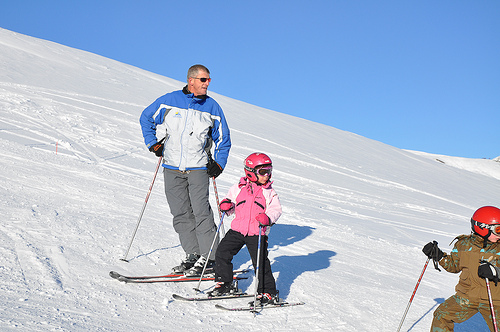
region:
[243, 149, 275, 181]
the helmet is red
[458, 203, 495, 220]
thehelmet is red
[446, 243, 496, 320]
the jacket is brown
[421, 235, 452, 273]
the gloves are black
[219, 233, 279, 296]
the pants are black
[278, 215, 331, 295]
shadowsa re on the ground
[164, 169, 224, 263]
the pants are grey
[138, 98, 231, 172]
the jacket is blue and white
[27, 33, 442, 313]
the hill is sloppy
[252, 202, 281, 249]
the gloves are red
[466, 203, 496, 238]
red ski helmet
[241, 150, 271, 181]
pink ski helmet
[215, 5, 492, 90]
clear light blue sky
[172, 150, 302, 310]
girl skier looking down a mountain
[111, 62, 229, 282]
male skier looking down a mountain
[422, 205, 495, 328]
skier wearing brown ski suit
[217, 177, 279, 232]
girl wearing pink ski jacket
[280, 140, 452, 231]
ski tracks in the snow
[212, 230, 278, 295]
girl wearing black ski pants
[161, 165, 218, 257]
man wearing grey ski pants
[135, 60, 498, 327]
Family members skiing together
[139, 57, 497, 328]
Three skiers looking downhill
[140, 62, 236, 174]
Man wearing blue and white jacket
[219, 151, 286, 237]
Young girl wearing pink coat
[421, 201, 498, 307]
Young boy wearing brown coat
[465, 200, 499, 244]
Young boy wearing red helmet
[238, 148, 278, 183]
Young girl wearing pink helmet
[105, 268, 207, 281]
Red and black skis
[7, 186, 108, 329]
White powdery snow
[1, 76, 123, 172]
White snow with ski tracks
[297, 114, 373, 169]
snow covered mountain range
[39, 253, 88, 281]
ski marks in the snow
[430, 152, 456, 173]
black rock in the snow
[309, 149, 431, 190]
line cutting across the white snow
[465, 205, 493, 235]
shiny red and black helmet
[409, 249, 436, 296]
red and silver ski pole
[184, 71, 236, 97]
black goggles around man's face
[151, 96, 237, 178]
blue and white ski jacket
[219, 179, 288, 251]
pink and black jacket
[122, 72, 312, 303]
skier standing on snow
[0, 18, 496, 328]
adult and two children on snowy hill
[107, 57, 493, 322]
all heads turned to the same side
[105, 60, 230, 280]
adult in blue and white jacket with gray pants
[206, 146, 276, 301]
child in pink and black outfit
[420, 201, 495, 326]
child in red helmet and brown jumpsuit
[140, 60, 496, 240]
skiers wearing goggles or sunglasses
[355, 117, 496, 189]
white hill behind slope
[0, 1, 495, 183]
clear blue sky over top of slopes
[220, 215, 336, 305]
shadows in back of skiers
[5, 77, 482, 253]
ski lines made across the snow